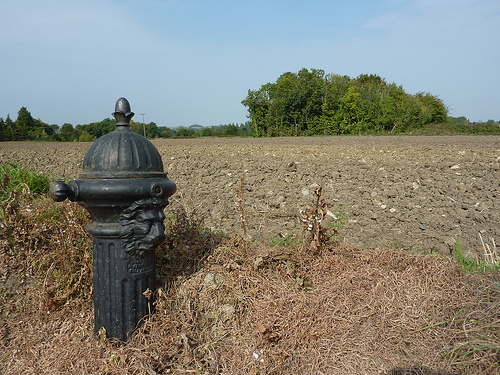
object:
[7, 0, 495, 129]
cloud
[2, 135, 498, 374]
dry field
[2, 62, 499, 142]
forest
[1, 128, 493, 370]
farm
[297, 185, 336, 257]
weed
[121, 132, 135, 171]
line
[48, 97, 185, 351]
post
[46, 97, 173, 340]
pillar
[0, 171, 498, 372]
grass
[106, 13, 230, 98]
blue sky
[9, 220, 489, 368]
dead grass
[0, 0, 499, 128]
sky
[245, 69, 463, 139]
hill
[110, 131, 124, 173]
line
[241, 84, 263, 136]
trees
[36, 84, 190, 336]
fire hydrant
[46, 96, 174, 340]
cast iron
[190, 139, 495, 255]
dirt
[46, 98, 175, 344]
hydrant